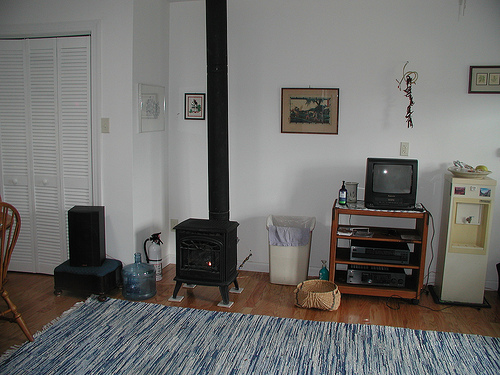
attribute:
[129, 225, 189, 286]
hydrant — white, black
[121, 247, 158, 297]
waterbottle — blue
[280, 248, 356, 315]
basket — wicker 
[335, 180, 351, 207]
bottle — black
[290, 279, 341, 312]
basket — wicker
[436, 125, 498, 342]
cooler — white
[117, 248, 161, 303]
gallon — water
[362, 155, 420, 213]
tv — off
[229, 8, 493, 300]
wall — clean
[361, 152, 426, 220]
television — small, black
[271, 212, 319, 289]
trash can — white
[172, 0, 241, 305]
heater — black, cast iron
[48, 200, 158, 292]
speaker — black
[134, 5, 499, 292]
wall — white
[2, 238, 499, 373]
floor — brown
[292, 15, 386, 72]
wall — white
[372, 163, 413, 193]
screen — off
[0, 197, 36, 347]
chair — brown, wooden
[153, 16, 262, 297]
chimney — black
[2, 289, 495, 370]
carpet — blue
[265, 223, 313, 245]
towel — White , folded 